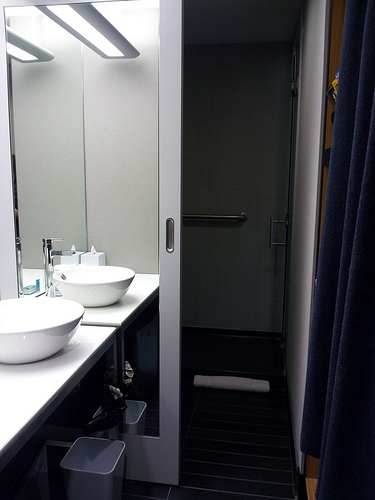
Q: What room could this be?
A: It is a bathroom.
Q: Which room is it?
A: It is a bathroom.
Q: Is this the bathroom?
A: Yes, it is the bathroom.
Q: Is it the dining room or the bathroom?
A: It is the bathroom.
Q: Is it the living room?
A: No, it is the bathroom.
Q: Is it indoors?
A: Yes, it is indoors.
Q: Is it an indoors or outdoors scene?
A: It is indoors.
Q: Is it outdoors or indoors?
A: It is indoors.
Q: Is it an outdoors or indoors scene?
A: It is indoors.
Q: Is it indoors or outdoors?
A: It is indoors.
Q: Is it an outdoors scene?
A: No, it is indoors.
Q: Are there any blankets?
A: No, there are no blankets.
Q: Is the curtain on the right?
A: Yes, the curtain is on the right of the image.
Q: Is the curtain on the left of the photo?
A: No, the curtain is on the right of the image.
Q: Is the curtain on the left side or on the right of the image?
A: The curtain is on the right of the image.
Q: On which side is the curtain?
A: The curtain is on the right of the image.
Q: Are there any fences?
A: No, there are no fences.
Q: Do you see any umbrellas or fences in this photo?
A: No, there are no fences or umbrellas.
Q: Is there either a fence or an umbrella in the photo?
A: No, there are no fences or umbrellas.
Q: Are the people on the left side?
A: Yes, the people are on the left of the image.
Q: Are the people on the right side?
A: No, the people are on the left of the image.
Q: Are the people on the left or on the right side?
A: The people are on the left of the image.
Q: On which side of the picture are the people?
A: The people are on the left of the image.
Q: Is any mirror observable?
A: Yes, there is a mirror.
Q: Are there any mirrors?
A: Yes, there is a mirror.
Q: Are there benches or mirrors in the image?
A: Yes, there is a mirror.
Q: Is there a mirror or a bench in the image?
A: Yes, there is a mirror.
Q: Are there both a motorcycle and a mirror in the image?
A: No, there is a mirror but no motorcycles.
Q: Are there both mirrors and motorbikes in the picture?
A: No, there is a mirror but no motorcycles.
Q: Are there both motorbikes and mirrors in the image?
A: No, there is a mirror but no motorcycles.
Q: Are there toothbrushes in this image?
A: No, there are no toothbrushes.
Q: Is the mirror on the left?
A: Yes, the mirror is on the left of the image.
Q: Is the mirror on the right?
A: No, the mirror is on the left of the image.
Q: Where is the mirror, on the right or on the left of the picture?
A: The mirror is on the left of the image.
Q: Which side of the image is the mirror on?
A: The mirror is on the left of the image.